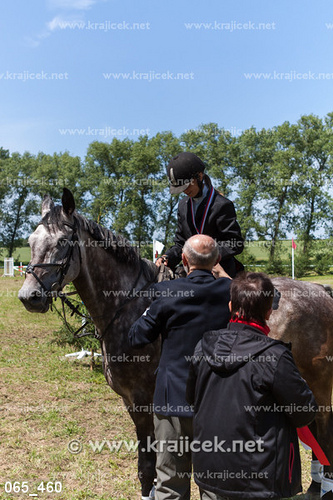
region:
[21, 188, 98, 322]
gray horse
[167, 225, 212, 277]
bald man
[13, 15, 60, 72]
white clouds in blue sky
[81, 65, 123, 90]
white clouds in blue sky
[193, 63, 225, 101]
white clouds in blue sky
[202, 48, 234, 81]
white clouds in blue sky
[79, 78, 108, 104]
white clouds in blue sky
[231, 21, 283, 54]
white clouds in blue sky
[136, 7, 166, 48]
white clouds in blue sky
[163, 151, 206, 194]
Black jockey hat on a head.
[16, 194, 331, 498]
A grey and black horse with brownish back legs.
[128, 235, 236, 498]
A grey haired balding man with a black jacket on.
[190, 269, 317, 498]
A brown haired person in a red and black jacket.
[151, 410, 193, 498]
Grey pants on a balding grey haired man.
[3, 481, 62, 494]
The number 065 460.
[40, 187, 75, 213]
A grey ear and a black ear on a horses head.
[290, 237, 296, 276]
A grey pole with a red flag.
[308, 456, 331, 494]
Two white wraps on a horses back legs.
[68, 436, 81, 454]
A grey copyright symbol.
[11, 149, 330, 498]
three men and a horse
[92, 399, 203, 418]
water mark on a photo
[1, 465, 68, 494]
photo number in the corner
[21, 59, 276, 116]
clear blue sky in the distance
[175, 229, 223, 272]
bald head of a man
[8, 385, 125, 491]
brown grass on the ground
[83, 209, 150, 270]
mane of a horse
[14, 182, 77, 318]
head of a horse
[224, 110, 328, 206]
green leaves on a tree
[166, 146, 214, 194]
hat on a jockey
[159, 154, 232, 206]
black helmet on top of head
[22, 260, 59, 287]
bridle on horses head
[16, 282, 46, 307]
nostrils on the nose of a horse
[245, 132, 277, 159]
tall tree with green leaves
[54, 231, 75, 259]
left eye on horse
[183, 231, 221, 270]
balding head of man facing away from camera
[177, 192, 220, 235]
red white and blue metal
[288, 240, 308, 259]
orange flag in the distance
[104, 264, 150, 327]
dark reins on horses back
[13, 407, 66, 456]
dying grass on ground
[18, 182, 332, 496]
brown horse in field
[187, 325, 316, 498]
black jacket with hood on person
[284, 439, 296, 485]
red lined pocket on black jacket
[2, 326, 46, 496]
patch of green grass on field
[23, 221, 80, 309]
black harnass on horse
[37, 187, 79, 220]
two pointed upright horse ears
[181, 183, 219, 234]
red, white and blue medal ribbon around jockey's neck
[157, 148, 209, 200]
black hat on top of jockey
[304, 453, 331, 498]
white wraps on lower leg of horses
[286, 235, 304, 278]
red flag on metal pole in green field